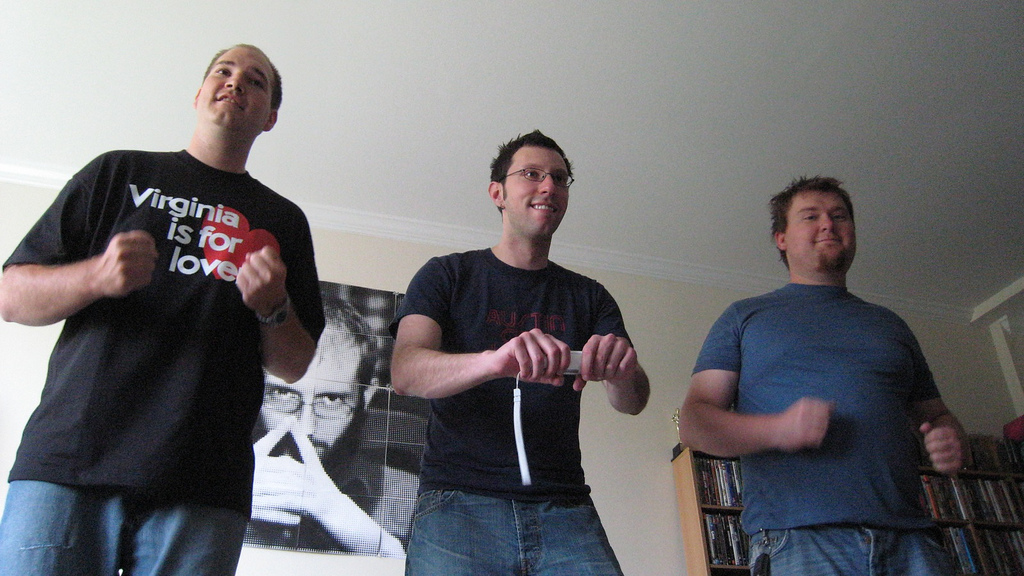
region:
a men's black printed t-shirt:
[392, 245, 634, 499]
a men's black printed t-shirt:
[2, 152, 325, 517]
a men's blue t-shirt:
[695, 286, 945, 527]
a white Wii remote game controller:
[512, 348, 586, 489]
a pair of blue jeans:
[401, 491, 620, 574]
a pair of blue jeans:
[746, 523, 952, 574]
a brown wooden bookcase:
[675, 432, 1023, 573]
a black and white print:
[237, 280, 438, 556]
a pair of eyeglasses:
[503, 165, 576, 185]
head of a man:
[89, 3, 349, 175]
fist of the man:
[190, 224, 320, 361]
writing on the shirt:
[98, 130, 295, 346]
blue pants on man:
[391, 453, 648, 572]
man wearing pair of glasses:
[360, 135, 671, 443]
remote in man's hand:
[460, 303, 631, 463]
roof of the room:
[558, 29, 767, 150]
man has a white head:
[491, 131, 574, 234]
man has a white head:
[195, 43, 284, 133]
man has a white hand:
[236, 248, 288, 306]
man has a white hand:
[109, 232, 152, 297]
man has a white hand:
[495, 327, 568, 388]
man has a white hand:
[788, 398, 836, 449]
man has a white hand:
[918, 419, 963, 470]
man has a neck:
[499, 221, 550, 266]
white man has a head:
[486, 129, 572, 238]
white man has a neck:
[494, 223, 552, 265]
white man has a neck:
[789, 262, 850, 288]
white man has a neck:
[192, 122, 249, 173]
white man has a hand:
[235, 240, 283, 308]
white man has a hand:
[502, 328, 567, 380]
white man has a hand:
[570, 331, 638, 398]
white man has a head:
[197, 47, 283, 143]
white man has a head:
[491, 129, 569, 231]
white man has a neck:
[498, 223, 550, 266]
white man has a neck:
[789, 261, 846, 288]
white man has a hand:
[97, 227, 152, 292]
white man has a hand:
[491, 324, 569, 385]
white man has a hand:
[570, 331, 635, 393]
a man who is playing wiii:
[372, 99, 692, 571]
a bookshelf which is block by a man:
[654, 412, 858, 571]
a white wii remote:
[501, 336, 628, 388]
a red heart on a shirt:
[194, 186, 297, 305]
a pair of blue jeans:
[385, 469, 632, 569]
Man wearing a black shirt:
[13, 132, 336, 535]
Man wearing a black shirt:
[379, 237, 629, 503]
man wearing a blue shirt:
[686, 272, 963, 529]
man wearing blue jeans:
[735, 518, 958, 573]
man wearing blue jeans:
[373, 477, 636, 567]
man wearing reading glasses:
[261, 385, 354, 430]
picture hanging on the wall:
[234, 252, 513, 560]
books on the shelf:
[932, 524, 1013, 563]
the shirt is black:
[3, 146, 326, 500]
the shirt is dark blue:
[391, 246, 633, 510]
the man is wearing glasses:
[389, 127, 652, 573]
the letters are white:
[128, 180, 239, 276]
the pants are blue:
[0, 477, 253, 573]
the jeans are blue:
[401, 486, 621, 573]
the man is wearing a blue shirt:
[676, 173, 967, 572]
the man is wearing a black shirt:
[0, 42, 324, 573]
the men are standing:
[0, 3, 1021, 572]